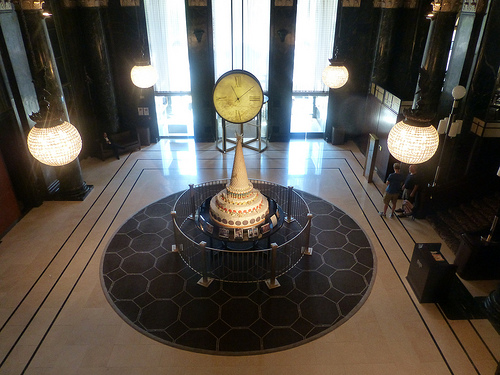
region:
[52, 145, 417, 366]
floor with large black circle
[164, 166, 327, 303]
metal railing forming a smaller circle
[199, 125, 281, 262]
round and flat object with a cone on top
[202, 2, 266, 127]
lighted clock suspended over cone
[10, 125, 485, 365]
three black lines form a rectangle around black circle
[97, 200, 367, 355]
pattern of squares and connected octagons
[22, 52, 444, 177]
lighted globes composed of pieces of glass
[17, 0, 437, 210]
dark columns in front of glass windows and walls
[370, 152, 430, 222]
two people in dark clothes by the wall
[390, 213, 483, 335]
a reception desk facing the center display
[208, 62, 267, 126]
The clock with the foru numbers on it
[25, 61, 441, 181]
The four lit lights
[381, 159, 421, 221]
The men standing in the room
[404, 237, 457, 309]
The small lectern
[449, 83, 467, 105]
The light that is not on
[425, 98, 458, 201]
The pole holding the unlit light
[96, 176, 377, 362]
The large brown circle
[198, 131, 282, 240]
The base of the clock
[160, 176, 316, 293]
The railing around the clock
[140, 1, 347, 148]
The larger than normal windows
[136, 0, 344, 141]
The large rectangular windows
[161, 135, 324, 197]
The sunlight reflecting off the ground inside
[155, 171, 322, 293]
The barrier around the clock tower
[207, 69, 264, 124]
The large clock with four numbers on it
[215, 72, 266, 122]
this is a clock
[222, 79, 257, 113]
the front is made of glass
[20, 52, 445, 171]
these are bulbs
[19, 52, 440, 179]
the bulbs are big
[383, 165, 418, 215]
these are two people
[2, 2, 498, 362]
this is a building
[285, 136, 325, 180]
the floor is shiny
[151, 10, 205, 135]
this is the door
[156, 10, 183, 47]
the door is made of glass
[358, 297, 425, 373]
the floor is slippery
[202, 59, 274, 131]
clock in middle of room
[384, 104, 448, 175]
illuminated glove light from ceiling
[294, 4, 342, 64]
windows in the back of room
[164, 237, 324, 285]
circular fence around clock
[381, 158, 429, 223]
people standing in lobby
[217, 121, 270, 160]
revolving doors to lobby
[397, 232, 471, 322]
front desk of a lobby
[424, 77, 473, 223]
light on a pole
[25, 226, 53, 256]
beige floor in a lobby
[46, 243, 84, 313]
black stripes on a floor